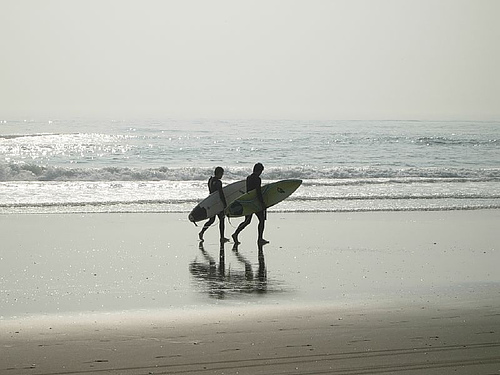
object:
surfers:
[231, 163, 269, 246]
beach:
[0, 211, 500, 375]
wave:
[0, 157, 500, 214]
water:
[0, 117, 500, 214]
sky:
[0, 0, 500, 124]